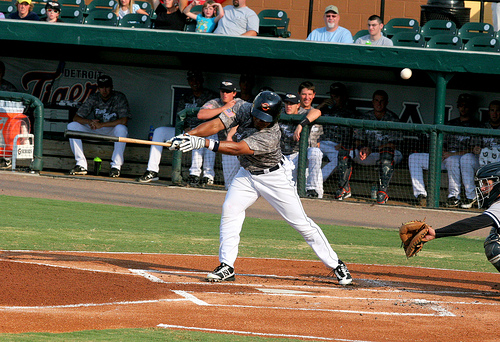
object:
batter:
[162, 83, 363, 293]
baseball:
[63, 81, 360, 297]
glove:
[398, 211, 429, 258]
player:
[63, 73, 131, 178]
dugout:
[8, 53, 487, 202]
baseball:
[396, 67, 415, 81]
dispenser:
[1, 99, 26, 161]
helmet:
[249, 88, 284, 130]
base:
[126, 269, 459, 321]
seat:
[427, 29, 464, 49]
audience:
[355, 15, 395, 48]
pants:
[218, 163, 342, 270]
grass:
[4, 199, 210, 256]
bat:
[61, 126, 173, 150]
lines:
[24, 256, 477, 328]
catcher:
[424, 159, 500, 279]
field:
[0, 175, 499, 328]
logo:
[20, 59, 106, 108]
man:
[336, 90, 408, 201]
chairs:
[390, 33, 421, 56]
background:
[5, 1, 495, 49]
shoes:
[372, 174, 390, 204]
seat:
[464, 29, 496, 50]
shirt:
[218, 98, 287, 175]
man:
[298, 6, 355, 46]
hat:
[323, 3, 341, 14]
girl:
[182, 1, 226, 32]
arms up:
[182, 2, 226, 18]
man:
[353, 14, 402, 50]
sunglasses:
[366, 21, 380, 27]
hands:
[167, 130, 211, 153]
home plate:
[258, 283, 320, 298]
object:
[90, 153, 103, 175]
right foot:
[202, 257, 240, 281]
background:
[3, 38, 496, 193]